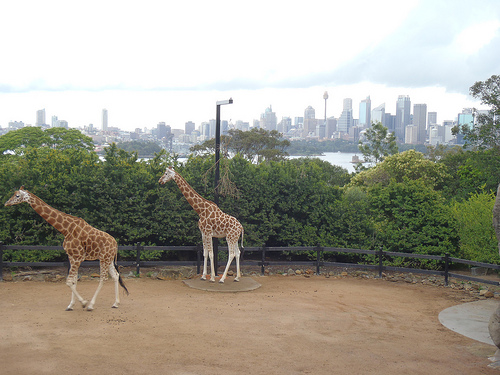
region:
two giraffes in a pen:
[8, 145, 272, 322]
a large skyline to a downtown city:
[31, 83, 488, 162]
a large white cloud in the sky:
[18, 32, 498, 110]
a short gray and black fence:
[8, 237, 498, 298]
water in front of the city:
[61, 124, 430, 189]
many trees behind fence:
[15, 123, 487, 257]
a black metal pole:
[205, 84, 241, 274]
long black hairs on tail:
[105, 261, 137, 302]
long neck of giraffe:
[20, 189, 76, 236]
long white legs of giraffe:
[190, 230, 250, 292]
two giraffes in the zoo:
[8, 152, 253, 314]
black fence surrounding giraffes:
[271, 235, 485, 296]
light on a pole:
[211, 92, 236, 206]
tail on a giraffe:
[231, 219, 250, 254]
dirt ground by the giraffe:
[207, 297, 410, 357]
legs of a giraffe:
[55, 260, 126, 320]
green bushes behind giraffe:
[320, 164, 490, 252]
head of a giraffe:
[151, 161, 181, 191]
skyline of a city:
[115, 101, 424, 162]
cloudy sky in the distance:
[198, 5, 480, 84]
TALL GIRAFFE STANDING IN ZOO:
[12, 175, 139, 301]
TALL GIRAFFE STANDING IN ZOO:
[141, 164, 251, 299]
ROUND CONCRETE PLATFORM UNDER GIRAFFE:
[180, 273, 280, 313]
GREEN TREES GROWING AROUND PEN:
[77, 162, 477, 273]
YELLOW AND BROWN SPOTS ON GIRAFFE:
[207, 216, 233, 236]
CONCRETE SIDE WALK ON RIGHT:
[424, 287, 495, 360]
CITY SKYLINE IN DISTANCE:
[63, 70, 455, 162]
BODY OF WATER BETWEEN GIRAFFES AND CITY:
[300, 139, 412, 185]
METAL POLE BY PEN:
[195, 75, 241, 187]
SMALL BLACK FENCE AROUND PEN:
[107, 221, 494, 279]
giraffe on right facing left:
[150, 163, 257, 287]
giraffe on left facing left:
[3, 185, 146, 322]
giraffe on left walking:
[0, 181, 139, 323]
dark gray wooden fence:
[2, 229, 499, 310]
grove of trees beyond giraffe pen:
[2, 72, 499, 299]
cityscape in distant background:
[0, 75, 498, 175]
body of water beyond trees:
[7, 142, 467, 186]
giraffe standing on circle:
[149, 161, 274, 304]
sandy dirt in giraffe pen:
[2, 241, 499, 372]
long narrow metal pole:
[212, 94, 232, 208]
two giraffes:
[1, 172, 308, 332]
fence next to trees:
[265, 245, 494, 290]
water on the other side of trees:
[242, 139, 388, 182]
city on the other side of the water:
[35, 108, 486, 149]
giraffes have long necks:
[156, 155, 208, 216]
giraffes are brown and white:
[198, 201, 225, 224]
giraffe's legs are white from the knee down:
[54, 281, 134, 319]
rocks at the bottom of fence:
[267, 264, 444, 294]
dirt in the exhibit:
[125, 309, 308, 374]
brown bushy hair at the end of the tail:
[111, 263, 139, 300]